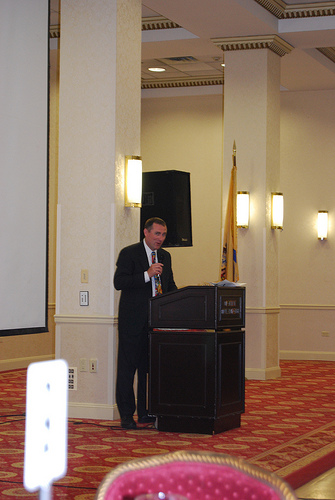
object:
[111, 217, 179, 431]
man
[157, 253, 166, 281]
mike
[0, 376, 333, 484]
carpet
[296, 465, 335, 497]
ground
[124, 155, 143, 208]
lamp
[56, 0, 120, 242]
wall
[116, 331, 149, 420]
pants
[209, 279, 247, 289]
paper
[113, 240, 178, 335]
jacket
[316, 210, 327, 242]
light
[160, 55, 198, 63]
vent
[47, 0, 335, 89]
ceiling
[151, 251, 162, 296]
necktie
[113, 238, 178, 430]
suit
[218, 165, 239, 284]
flag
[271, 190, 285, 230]
light fixture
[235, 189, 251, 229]
light fixture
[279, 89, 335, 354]
wall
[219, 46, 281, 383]
pillar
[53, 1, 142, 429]
pillar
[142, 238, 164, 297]
dress shirt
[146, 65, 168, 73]
light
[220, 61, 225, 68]
light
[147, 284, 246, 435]
lectern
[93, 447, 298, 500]
chair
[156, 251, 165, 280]
microphone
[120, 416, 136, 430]
shoe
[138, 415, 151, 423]
shoe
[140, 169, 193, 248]
object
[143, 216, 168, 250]
head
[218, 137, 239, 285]
flag